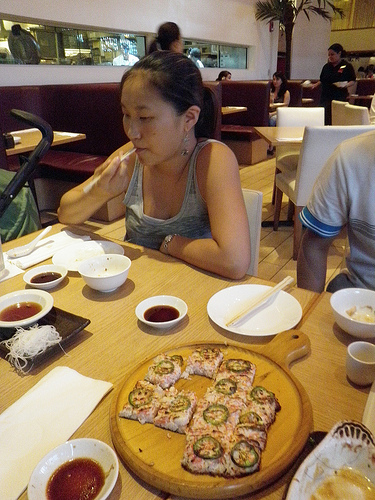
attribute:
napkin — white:
[1, 365, 114, 498]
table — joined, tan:
[1, 222, 373, 500]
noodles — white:
[0, 323, 64, 375]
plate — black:
[0, 306, 91, 361]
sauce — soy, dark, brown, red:
[144, 305, 180, 321]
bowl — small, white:
[134, 295, 188, 330]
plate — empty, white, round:
[208, 282, 302, 338]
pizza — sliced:
[118, 348, 281, 479]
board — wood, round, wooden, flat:
[109, 330, 314, 499]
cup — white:
[346, 340, 373, 388]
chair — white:
[272, 125, 375, 261]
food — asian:
[1, 225, 373, 499]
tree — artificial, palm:
[254, 0, 346, 81]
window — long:
[1, 14, 149, 67]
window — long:
[181, 36, 247, 70]